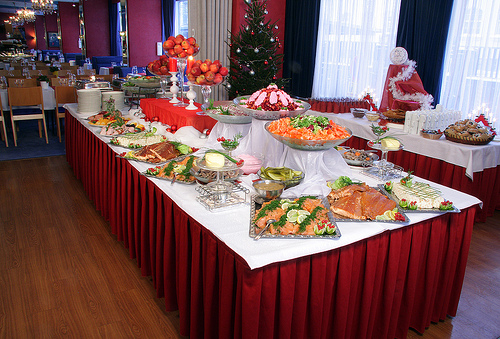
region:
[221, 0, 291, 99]
the christmas tree along the wall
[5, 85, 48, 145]
the empty chair at the table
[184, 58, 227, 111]
the fruit in the bowl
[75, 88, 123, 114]
the stack of plates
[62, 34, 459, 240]
the food on the table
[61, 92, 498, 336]
the red skirts on the tables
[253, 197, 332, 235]
the food on the silver tray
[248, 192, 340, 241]
the silver tray under the food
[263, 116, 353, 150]
the large bowl on the table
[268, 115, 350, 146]
the food in the large bowl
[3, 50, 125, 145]
wooden chairs at dinner tables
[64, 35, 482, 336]
a table full of food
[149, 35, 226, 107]
display bowls of whole fruit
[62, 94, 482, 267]
a white tablecloth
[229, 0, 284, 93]
a christmas tree with decorations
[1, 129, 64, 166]
hardwood and blue carpet transition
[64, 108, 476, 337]
red tablecloth under white topping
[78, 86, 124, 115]
stacks of white plates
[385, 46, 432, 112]
a red christmas decoration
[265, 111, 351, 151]
a glass dish of orange food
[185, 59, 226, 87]
The bowl has a lot of apples.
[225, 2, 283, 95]
The Christmas Tree has white and red ornaments.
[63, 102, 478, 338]
The table cloth is red and white.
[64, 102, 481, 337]
The table is full of a lot of food.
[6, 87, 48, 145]
The chair is made of wood.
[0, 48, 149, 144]
The chairs are empty.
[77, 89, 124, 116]
The dishes are white.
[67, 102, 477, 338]
The table is near to the chairs.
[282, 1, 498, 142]
The curtains are white and blue.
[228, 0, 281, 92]
The Christmas Tree is very little.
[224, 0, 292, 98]
A Christmas tree with ornaments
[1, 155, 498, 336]
A brown wooden floor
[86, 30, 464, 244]
A lot of food on the table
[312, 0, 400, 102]
White curtains over a window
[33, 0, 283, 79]
The walls are red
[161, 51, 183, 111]
Red candle on white candlestick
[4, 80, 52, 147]
A brown wooden chair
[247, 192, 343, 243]
Food on a tray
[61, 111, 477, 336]
A red tablecloth around the table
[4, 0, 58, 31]
Lights on the ceiling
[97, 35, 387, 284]
Food on the table.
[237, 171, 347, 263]
Plate of food on the table.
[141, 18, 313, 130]
Fruit on the table.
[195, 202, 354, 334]
Red table cloth.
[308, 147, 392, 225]
Meat on the tray,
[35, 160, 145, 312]
Wood on the floor.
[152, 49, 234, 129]
Candles on the banquet table.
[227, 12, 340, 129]
Christmas tree by the window.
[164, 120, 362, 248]
White cloth on the table.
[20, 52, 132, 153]
Chairs by the table.